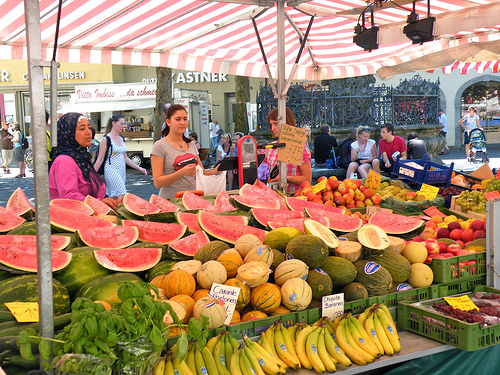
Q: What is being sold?
A: Fruit.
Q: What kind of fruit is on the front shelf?
A: Bananas.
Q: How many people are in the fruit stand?
A: 2.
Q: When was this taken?
A: Daytime.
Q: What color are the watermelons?
A: Green and pink.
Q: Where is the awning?
A: Above the stand.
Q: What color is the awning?
A: Pink and white.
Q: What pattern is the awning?
A: Stripes.